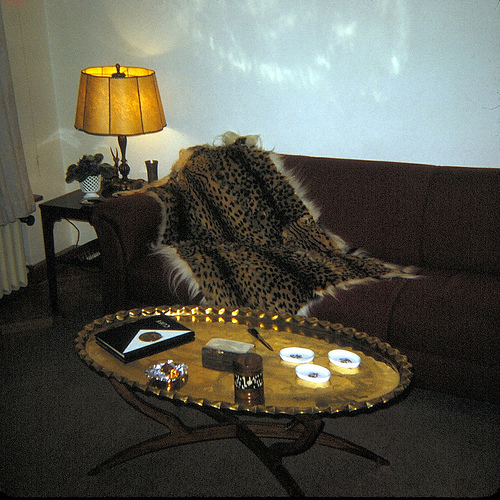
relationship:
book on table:
[90, 313, 204, 362] [77, 306, 417, 419]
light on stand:
[73, 65, 168, 192] [40, 187, 83, 325]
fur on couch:
[137, 141, 414, 320] [89, 145, 493, 394]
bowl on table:
[329, 343, 360, 373] [77, 306, 417, 419]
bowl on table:
[298, 365, 332, 385] [77, 306, 417, 419]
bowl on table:
[281, 343, 314, 365] [77, 306, 417, 419]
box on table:
[200, 330, 256, 372] [77, 306, 417, 419]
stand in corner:
[40, 187, 83, 325] [42, 19, 69, 124]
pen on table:
[250, 324, 275, 353] [77, 306, 417, 419]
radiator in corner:
[0, 228, 33, 299] [42, 19, 69, 124]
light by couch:
[73, 65, 168, 192] [89, 145, 493, 394]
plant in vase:
[66, 147, 115, 180] [83, 174, 101, 199]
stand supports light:
[40, 187, 83, 325] [73, 65, 168, 192]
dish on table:
[149, 362, 192, 385] [77, 306, 417, 419]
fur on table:
[137, 141, 414, 320] [77, 306, 417, 419]